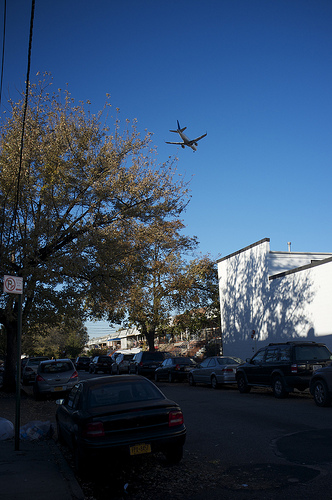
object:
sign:
[3, 274, 25, 295]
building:
[216, 237, 332, 365]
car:
[53, 373, 187, 493]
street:
[42, 363, 331, 499]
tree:
[0, 69, 195, 403]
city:
[1, 1, 331, 499]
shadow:
[216, 244, 316, 365]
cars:
[38, 353, 78, 388]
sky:
[1, 0, 331, 341]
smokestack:
[285, 238, 293, 253]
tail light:
[168, 408, 184, 429]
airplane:
[163, 120, 208, 154]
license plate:
[128, 442, 153, 456]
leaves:
[1, 372, 291, 499]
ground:
[0, 367, 330, 496]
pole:
[13, 293, 23, 450]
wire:
[10, 0, 35, 213]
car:
[185, 354, 243, 388]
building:
[83, 304, 223, 359]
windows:
[84, 379, 165, 416]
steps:
[181, 339, 216, 362]